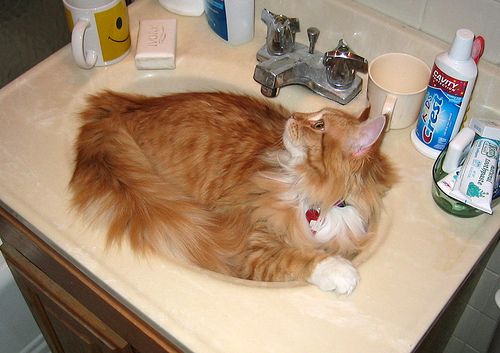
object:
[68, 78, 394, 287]
cat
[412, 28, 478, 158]
tooth paste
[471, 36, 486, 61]
toothbrush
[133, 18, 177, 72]
soap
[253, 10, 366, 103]
tap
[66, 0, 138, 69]
mug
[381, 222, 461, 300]
counter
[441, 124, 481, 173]
floss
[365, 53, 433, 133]
mug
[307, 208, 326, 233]
item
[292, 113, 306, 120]
nose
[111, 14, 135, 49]
smiley face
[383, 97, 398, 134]
handle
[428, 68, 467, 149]
label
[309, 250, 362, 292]
paw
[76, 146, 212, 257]
tail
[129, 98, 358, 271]
sink